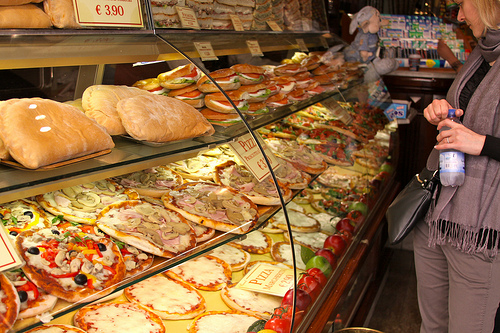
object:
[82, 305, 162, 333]
pizza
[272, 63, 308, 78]
sandwiches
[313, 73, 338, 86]
sandwich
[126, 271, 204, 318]
pizza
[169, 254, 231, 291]
pizza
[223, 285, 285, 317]
pizza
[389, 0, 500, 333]
woman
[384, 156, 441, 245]
purse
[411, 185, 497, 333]
gray pants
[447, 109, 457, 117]
cap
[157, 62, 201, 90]
sandwich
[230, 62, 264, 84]
sandwich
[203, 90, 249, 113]
sandwich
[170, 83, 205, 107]
sandwich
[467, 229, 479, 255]
fringe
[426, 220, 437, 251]
fringe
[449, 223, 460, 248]
fringe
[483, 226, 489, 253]
fringe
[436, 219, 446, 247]
fringe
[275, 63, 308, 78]
sandwich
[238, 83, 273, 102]
sandwich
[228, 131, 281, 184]
price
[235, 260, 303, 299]
price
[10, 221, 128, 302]
pizza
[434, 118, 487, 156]
hand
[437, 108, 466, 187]
bottle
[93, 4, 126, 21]
price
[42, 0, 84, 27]
product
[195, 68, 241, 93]
sandwich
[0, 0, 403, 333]
display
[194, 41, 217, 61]
sign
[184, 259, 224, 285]
cheese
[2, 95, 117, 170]
calzone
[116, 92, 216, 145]
calzone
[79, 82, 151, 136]
calzone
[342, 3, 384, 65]
doll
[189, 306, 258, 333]
pizza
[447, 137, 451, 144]
band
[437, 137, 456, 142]
finger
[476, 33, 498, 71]
scarf/woman's neck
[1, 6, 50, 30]
calzones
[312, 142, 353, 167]
cheese pizza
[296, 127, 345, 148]
cheese pizza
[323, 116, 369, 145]
cheese pizza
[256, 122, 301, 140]
cheese pizza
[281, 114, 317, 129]
cheese pizza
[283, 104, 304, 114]
glass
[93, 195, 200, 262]
pizza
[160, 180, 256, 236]
pizza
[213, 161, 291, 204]
pizza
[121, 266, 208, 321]
pizza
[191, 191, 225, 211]
toppings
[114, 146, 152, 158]
glass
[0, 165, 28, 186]
glass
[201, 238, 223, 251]
glass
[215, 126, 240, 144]
glass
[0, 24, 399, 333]
shelf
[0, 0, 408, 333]
case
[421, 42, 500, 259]
scarf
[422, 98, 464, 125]
hands